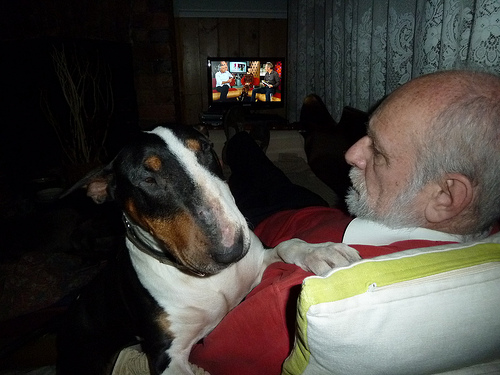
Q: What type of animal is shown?
A: Dog.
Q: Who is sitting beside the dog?
A: An old man.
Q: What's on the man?
A: Dog.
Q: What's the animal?
A: Dog.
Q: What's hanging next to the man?
A: Curtain.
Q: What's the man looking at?
A: The dog.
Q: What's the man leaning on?
A: Pillow.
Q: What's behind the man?
A: Pillow.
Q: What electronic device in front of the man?
A: Television.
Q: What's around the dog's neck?
A: Collar.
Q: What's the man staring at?
A: Dog.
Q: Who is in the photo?
A: A man.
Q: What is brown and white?
A: The dog.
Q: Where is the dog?
A: Next to man.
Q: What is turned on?
A: Television.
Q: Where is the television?
A: In the room.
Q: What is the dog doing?
A: Sitting next to man.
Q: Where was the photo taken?
A: In a room.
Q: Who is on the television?
A: Some people.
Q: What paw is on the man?
A: Left.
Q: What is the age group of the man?
A: Elderly.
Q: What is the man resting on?
A: A pillow.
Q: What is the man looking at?
A: The dog.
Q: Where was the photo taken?
A: In a room.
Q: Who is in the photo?
A: A man and a dog.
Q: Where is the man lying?
A: On a sofa.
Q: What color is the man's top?
A: Dark red.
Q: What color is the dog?
A: White and black and brown.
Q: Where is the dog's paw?
A: On the man's shoulder.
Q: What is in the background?
A: A television.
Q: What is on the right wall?
A: Drapes.